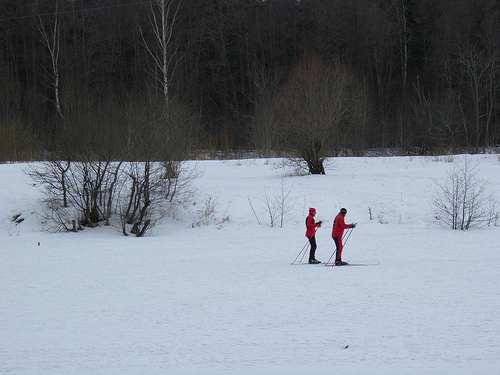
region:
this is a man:
[331, 187, 357, 266]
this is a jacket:
[334, 220, 344, 228]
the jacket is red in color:
[331, 219, 341, 234]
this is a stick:
[283, 236, 306, 274]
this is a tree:
[278, 63, 326, 144]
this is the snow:
[352, 269, 430, 363]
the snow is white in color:
[336, 280, 429, 334]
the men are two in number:
[291, 200, 367, 275]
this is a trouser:
[333, 239, 343, 264]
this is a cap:
[306, 205, 320, 212]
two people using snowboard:
[298, 207, 361, 279]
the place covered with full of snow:
[72, 267, 433, 346]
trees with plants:
[41, 129, 179, 224]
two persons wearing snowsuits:
[293, 196, 358, 267]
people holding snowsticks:
[295, 241, 305, 268]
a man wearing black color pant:
[305, 235, 324, 267]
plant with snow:
[435, 156, 482, 242]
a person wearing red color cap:
[306, 205, 316, 215]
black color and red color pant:
[331, 231, 348, 268]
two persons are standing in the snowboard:
[300, 202, 371, 271]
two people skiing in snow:
[281, 200, 368, 275]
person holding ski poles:
[289, 201, 327, 269]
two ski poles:
[289, 219, 329, 268]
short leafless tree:
[421, 159, 495, 245]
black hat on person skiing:
[336, 205, 349, 217]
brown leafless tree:
[258, 50, 372, 187]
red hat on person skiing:
[303, 205, 323, 217]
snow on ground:
[4, 147, 492, 372]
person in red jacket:
[303, 213, 323, 238]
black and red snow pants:
[328, 237, 349, 263]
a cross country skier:
[292, 206, 328, 265]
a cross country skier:
[322, 208, 372, 268]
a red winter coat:
[305, 214, 321, 236]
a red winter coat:
[333, 214, 352, 235]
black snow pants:
[305, 236, 318, 259]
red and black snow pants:
[332, 236, 344, 261]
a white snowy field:
[2, 161, 497, 371]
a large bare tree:
[249, 57, 369, 174]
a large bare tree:
[134, 0, 185, 103]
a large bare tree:
[22, 3, 74, 130]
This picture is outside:
[45, 31, 489, 342]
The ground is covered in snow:
[34, 224, 285, 372]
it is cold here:
[62, 43, 488, 333]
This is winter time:
[48, 60, 471, 373]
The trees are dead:
[30, 35, 498, 192]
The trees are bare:
[30, 21, 499, 141]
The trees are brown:
[36, 35, 461, 149]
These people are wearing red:
[294, 205, 396, 284]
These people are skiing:
[275, 196, 400, 297]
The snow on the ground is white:
[58, 243, 383, 374]